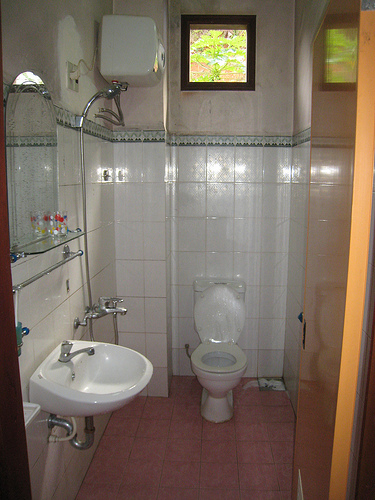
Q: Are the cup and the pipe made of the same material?
A: No, the cup is made of glass and the pipe is made of metal.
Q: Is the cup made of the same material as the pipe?
A: No, the cup is made of glass and the pipe is made of metal.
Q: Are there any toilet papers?
A: No, there are no toilet papers.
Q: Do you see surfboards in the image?
A: No, there are no surfboards.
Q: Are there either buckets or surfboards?
A: No, there are no surfboards or buckets.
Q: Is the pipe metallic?
A: Yes, the pipe is metallic.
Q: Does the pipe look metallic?
A: Yes, the pipe is metallic.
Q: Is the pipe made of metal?
A: Yes, the pipe is made of metal.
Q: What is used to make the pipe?
A: The pipe is made of metal.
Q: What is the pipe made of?
A: The pipe is made of metal.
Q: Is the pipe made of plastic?
A: No, the pipe is made of metal.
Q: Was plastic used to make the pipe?
A: No, the pipe is made of metal.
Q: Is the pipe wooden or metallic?
A: The pipe is metallic.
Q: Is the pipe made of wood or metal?
A: The pipe is made of metal.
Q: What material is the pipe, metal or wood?
A: The pipe is made of metal.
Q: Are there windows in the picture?
A: Yes, there is a window.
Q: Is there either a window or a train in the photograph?
A: Yes, there is a window.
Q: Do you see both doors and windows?
A: Yes, there are both a window and doors.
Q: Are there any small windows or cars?
A: Yes, there is a small window.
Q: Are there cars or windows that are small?
A: Yes, the window is small.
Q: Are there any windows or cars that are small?
A: Yes, the window is small.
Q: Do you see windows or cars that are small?
A: Yes, the window is small.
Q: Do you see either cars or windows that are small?
A: Yes, the window is small.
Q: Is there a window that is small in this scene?
A: Yes, there is a small window.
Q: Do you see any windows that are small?
A: Yes, there is a window that is small.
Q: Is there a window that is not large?
A: Yes, there is a small window.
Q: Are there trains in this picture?
A: No, there are no trains.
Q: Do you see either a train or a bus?
A: No, there are no trains or buses.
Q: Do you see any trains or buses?
A: No, there are no trains or buses.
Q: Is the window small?
A: Yes, the window is small.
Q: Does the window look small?
A: Yes, the window is small.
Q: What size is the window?
A: The window is small.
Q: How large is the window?
A: The window is small.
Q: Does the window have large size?
A: No, the window is small.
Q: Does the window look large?
A: No, the window is small.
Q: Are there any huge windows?
A: No, there is a window but it is small.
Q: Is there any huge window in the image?
A: No, there is a window but it is small.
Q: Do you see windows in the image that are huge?
A: No, there is a window but it is small.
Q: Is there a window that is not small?
A: No, there is a window but it is small.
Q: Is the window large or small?
A: The window is small.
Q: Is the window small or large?
A: The window is small.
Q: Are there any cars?
A: No, there are no cars.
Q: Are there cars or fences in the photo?
A: No, there are no cars or fences.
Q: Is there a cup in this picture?
A: Yes, there is a cup.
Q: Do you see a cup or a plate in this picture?
A: Yes, there is a cup.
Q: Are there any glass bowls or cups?
A: Yes, there is a glass cup.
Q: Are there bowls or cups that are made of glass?
A: Yes, the cup is made of glass.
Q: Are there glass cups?
A: Yes, there is a cup that is made of glass.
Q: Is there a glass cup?
A: Yes, there is a cup that is made of glass.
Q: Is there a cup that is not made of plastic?
A: Yes, there is a cup that is made of glass.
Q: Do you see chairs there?
A: No, there are no chairs.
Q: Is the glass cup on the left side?
A: Yes, the cup is on the left of the image.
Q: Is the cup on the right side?
A: No, the cup is on the left of the image.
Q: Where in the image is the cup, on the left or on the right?
A: The cup is on the left of the image.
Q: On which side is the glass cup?
A: The cup is on the left of the image.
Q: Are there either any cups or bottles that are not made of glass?
A: No, there is a cup but it is made of glass.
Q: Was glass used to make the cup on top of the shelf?
A: Yes, the cup is made of glass.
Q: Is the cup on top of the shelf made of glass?
A: Yes, the cup is made of glass.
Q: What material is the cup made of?
A: The cup is made of glass.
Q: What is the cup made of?
A: The cup is made of glass.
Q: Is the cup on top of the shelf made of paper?
A: No, the cup is made of glass.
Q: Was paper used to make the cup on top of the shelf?
A: No, the cup is made of glass.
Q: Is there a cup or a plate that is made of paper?
A: No, there is a cup but it is made of glass.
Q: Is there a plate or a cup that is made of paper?
A: No, there is a cup but it is made of glass.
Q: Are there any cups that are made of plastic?
A: No, there is a cup but it is made of glass.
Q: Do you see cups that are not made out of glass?
A: No, there is a cup but it is made of glass.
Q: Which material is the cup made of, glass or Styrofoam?
A: The cup is made of glass.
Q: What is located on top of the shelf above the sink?
A: The cup is on top of the shelf.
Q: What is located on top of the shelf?
A: The cup is on top of the shelf.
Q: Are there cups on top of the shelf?
A: Yes, there is a cup on top of the shelf.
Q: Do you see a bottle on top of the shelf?
A: No, there is a cup on top of the shelf.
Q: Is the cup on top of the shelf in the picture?
A: Yes, the cup is on top of the shelf.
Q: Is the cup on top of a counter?
A: No, the cup is on top of the shelf.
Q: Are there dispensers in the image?
A: No, there are no dispensers.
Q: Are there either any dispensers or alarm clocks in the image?
A: No, there are no dispensers or alarm clocks.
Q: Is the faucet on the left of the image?
A: Yes, the faucet is on the left of the image.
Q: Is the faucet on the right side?
A: No, the faucet is on the left of the image.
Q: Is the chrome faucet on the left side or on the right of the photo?
A: The faucet is on the left of the image.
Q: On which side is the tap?
A: The tap is on the left of the image.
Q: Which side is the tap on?
A: The tap is on the left of the image.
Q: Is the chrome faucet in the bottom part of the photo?
A: Yes, the faucet is in the bottom of the image.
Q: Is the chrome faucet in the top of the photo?
A: No, the tap is in the bottom of the image.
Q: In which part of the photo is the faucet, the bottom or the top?
A: The faucet is in the bottom of the image.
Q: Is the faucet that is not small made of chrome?
A: Yes, the tap is made of chrome.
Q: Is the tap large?
A: Yes, the tap is large.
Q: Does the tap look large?
A: Yes, the tap is large.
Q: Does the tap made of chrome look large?
A: Yes, the tap is large.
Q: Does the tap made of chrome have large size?
A: Yes, the tap is large.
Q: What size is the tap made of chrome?
A: The tap is large.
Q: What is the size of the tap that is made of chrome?
A: The tap is large.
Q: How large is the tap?
A: The tap is large.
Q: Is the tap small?
A: No, the tap is large.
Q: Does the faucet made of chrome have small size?
A: No, the tap is large.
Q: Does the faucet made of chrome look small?
A: No, the tap is large.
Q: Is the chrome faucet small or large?
A: The tap is large.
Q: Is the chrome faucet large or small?
A: The tap is large.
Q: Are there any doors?
A: Yes, there is a door.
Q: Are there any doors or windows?
A: Yes, there is a door.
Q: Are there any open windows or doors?
A: Yes, there is an open door.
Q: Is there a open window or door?
A: Yes, there is an open door.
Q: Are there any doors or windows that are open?
A: Yes, the door is open.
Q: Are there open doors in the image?
A: Yes, there is an open door.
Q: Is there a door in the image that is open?
A: Yes, there is a door that is open.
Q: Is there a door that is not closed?
A: Yes, there is a open door.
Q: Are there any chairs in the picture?
A: No, there are no chairs.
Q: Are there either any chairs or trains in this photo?
A: No, there are no chairs or trains.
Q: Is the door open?
A: Yes, the door is open.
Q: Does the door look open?
A: Yes, the door is open.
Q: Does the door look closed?
A: No, the door is open.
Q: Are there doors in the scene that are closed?
A: No, there is a door but it is open.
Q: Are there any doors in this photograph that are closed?
A: No, there is a door but it is open.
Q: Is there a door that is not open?
A: No, there is a door but it is open.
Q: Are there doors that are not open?
A: No, there is a door but it is open.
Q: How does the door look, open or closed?
A: The door is open.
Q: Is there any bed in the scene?
A: No, there are no beds.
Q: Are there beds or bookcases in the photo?
A: No, there are no beds or bookcases.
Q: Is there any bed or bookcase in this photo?
A: No, there are no beds or bookcases.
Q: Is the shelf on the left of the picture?
A: Yes, the shelf is on the left of the image.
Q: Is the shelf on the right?
A: No, the shelf is on the left of the image.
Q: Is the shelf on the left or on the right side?
A: The shelf is on the left of the image.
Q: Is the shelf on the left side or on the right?
A: The shelf is on the left of the image.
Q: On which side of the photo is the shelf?
A: The shelf is on the left of the image.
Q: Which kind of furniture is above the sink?
A: The piece of furniture is a shelf.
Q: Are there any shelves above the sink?
A: Yes, there is a shelf above the sink.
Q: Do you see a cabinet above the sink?
A: No, there is a shelf above the sink.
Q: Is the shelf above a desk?
A: No, the shelf is above the sink.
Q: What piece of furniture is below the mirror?
A: The piece of furniture is a shelf.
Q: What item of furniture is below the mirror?
A: The piece of furniture is a shelf.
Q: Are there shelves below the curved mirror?
A: Yes, there is a shelf below the mirror.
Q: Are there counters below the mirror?
A: No, there is a shelf below the mirror.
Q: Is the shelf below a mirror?
A: Yes, the shelf is below a mirror.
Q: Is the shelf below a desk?
A: No, the shelf is below a mirror.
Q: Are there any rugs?
A: No, there are no rugs.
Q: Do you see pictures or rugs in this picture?
A: No, there are no rugs or pictures.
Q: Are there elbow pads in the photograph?
A: No, there are no elbow pads.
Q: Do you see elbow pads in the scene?
A: No, there are no elbow pads.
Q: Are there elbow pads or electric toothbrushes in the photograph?
A: No, there are no elbow pads or electric toothbrushes.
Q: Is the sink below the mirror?
A: Yes, the sink is below the mirror.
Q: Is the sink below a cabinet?
A: No, the sink is below the mirror.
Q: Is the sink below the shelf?
A: Yes, the sink is below the shelf.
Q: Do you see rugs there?
A: No, there are no rugs.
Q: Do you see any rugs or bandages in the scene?
A: No, there are no rugs or bandages.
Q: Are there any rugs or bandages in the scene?
A: No, there are no rugs or bandages.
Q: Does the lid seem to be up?
A: Yes, the lid is up.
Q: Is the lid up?
A: Yes, the lid is up.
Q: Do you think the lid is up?
A: Yes, the lid is up.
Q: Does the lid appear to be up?
A: Yes, the lid is up.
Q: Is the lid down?
A: No, the lid is up.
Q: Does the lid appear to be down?
A: No, the lid is up.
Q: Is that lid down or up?
A: The lid is up.